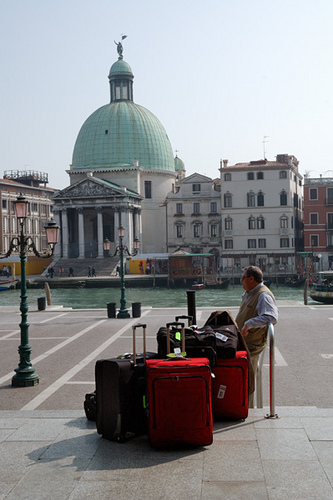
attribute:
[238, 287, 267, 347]
top — brown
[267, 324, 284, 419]
metal — silver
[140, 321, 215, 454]
luggage — red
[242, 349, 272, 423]
pants — brown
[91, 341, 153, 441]
luggage — black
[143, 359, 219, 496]
bag — red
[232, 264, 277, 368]
man — standing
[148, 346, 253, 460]
luggage — red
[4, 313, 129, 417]
line — white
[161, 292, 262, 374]
bag — red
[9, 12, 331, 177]
sky — daytime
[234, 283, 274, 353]
sweater vest — brown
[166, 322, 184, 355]
handle — up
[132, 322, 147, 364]
handle — up